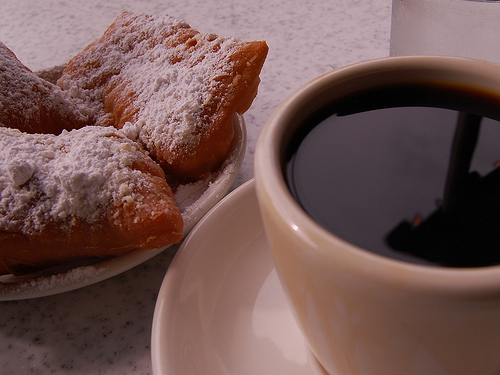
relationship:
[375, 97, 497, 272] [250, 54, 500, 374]
reflection in brown cup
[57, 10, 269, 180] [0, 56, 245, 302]
donut on dish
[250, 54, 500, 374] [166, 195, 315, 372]
brown cup on saucer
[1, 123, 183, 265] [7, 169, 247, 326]
donut on a plate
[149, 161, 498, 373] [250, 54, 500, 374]
saucer for brown cup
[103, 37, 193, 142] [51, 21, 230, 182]
powder on bread item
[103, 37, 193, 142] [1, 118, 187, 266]
powder on bread item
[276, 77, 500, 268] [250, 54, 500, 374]
black coffee in brown cup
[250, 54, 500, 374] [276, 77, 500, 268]
brown cup of black coffee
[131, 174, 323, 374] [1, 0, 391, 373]
plate on table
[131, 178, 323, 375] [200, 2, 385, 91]
plate on table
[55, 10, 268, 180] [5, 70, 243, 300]
donut on a plate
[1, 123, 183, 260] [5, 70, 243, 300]
donut on a plate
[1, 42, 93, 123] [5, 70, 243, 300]
donut on a plate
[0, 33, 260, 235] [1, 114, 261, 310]
treats on a plate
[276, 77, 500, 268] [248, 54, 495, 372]
black coffee inside cup[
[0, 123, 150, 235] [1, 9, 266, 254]
powder on top of pastry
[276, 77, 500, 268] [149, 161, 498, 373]
black coffee with saucer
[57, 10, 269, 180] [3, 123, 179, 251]
donut next to pastry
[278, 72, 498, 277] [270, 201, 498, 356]
black coffee in brown cup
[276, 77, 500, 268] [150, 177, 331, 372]
black coffee sitting on saucer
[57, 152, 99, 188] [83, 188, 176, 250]
powdered sugar on pastry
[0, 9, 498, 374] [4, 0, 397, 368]
breakfast on surface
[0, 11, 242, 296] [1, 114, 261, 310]
powdered sugar on plate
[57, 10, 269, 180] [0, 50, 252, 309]
donut on dish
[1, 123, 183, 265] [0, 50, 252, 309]
donut on dish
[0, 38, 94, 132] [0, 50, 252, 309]
donut on dish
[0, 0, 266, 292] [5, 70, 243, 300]
pastries on plate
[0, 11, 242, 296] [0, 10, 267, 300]
powdered sugar topping pastries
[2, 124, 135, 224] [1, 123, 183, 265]
topping on donut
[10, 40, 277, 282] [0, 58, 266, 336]
pastries on plate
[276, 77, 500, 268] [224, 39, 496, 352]
black coffee in cup